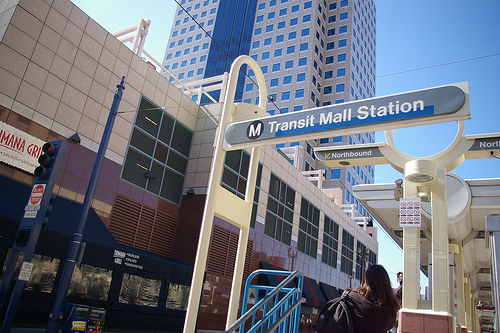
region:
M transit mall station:
[228, 95, 461, 129]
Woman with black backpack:
[331, 257, 405, 330]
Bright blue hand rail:
[223, 264, 311, 331]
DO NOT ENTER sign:
[23, 167, 62, 217]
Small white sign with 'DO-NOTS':
[386, 194, 426, 228]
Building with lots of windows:
[92, 93, 351, 255]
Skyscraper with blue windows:
[171, 0, 382, 114]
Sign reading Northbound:
[310, 141, 382, 168]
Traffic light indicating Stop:
[18, 120, 95, 242]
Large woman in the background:
[386, 265, 419, 309]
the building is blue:
[286, 37, 397, 105]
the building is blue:
[240, 27, 417, 189]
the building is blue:
[263, 57, 340, 104]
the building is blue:
[260, 2, 350, 82]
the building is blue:
[239, 62, 351, 159]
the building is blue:
[245, 18, 330, 53]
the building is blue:
[263, 30, 347, 70]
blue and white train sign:
[218, 78, 473, 145]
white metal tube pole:
[182, 53, 260, 331]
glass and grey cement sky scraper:
[163, 2, 376, 211]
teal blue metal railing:
[243, 265, 305, 332]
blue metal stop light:
[24, 138, 64, 178]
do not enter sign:
[26, 184, 46, 206]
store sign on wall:
[1, 119, 47, 179]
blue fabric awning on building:
[2, 176, 116, 268]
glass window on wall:
[119, 270, 164, 315]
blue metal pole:
[46, 75, 128, 318]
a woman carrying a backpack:
[321, 265, 396, 330]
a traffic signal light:
[31, 140, 69, 186]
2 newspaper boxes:
[59, 300, 113, 330]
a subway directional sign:
[216, 85, 471, 140]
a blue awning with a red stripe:
[302, 277, 325, 306]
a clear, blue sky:
[393, 17, 457, 62]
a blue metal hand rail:
[238, 271, 305, 331]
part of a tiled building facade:
[44, 44, 90, 124]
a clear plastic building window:
[122, 268, 162, 309]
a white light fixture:
[406, 154, 441, 183]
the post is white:
[175, 158, 277, 260]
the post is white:
[196, 180, 346, 324]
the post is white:
[146, 134, 383, 296]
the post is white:
[136, 221, 281, 303]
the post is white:
[136, 135, 256, 227]